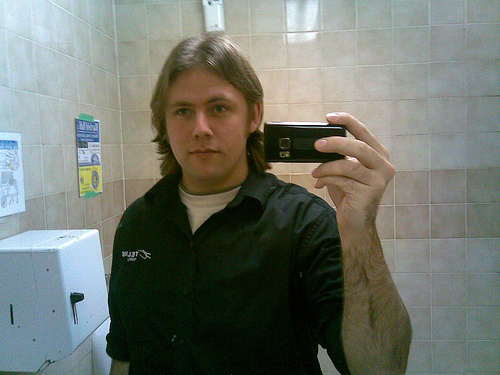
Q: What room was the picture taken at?
A: It was taken at the bathroom.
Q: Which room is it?
A: It is a bathroom.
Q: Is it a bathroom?
A: Yes, it is a bathroom.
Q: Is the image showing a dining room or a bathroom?
A: It is showing a bathroom.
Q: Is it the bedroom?
A: No, it is the bathroom.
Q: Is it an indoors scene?
A: Yes, it is indoors.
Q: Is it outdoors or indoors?
A: It is indoors.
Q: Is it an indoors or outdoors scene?
A: It is indoors.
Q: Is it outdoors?
A: No, it is indoors.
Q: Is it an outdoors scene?
A: No, it is indoors.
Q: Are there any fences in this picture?
A: No, there are no fences.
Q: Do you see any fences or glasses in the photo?
A: No, there are no fences or glasses.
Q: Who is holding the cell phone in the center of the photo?
A: The man is holding the cell phone.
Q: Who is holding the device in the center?
A: The man is holding the cell phone.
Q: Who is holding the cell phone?
A: The man is holding the cell phone.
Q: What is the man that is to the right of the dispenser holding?
A: The man is holding the cell phone.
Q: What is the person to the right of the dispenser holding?
A: The man is holding the cell phone.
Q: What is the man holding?
A: The man is holding the cell phone.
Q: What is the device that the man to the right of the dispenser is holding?
A: The device is a cell phone.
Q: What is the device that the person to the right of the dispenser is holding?
A: The device is a cell phone.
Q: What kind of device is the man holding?
A: The man is holding the cellphone.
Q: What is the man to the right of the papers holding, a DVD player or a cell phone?
A: The man is holding a cell phone.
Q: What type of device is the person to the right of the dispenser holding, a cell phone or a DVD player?
A: The man is holding a cell phone.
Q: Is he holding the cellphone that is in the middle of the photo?
A: Yes, the man is holding the cell phone.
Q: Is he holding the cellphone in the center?
A: Yes, the man is holding the cell phone.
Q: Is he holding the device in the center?
A: Yes, the man is holding the cell phone.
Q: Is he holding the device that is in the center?
A: Yes, the man is holding the cell phone.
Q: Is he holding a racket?
A: No, the man is holding the cell phone.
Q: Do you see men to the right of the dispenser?
A: Yes, there is a man to the right of the dispenser.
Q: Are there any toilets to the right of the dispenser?
A: No, there is a man to the right of the dispenser.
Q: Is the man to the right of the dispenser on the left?
A: Yes, the man is to the right of the dispenser.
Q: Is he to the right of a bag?
A: No, the man is to the right of the dispenser.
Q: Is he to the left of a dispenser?
A: No, the man is to the right of a dispenser.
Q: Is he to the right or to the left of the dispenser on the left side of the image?
A: The man is to the right of the dispenser.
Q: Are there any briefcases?
A: No, there are no briefcases.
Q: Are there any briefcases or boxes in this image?
A: No, there are no briefcases or boxes.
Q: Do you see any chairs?
A: No, there are no chairs.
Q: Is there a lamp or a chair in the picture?
A: No, there are no chairs or lamps.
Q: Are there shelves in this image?
A: No, there are no shelves.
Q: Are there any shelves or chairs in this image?
A: No, there are no shelves or chairs.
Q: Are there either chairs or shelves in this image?
A: No, there are no shelves or chairs.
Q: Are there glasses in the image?
A: No, there are no glasses.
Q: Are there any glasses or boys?
A: No, there are no glasses or boys.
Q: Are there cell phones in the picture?
A: Yes, there is a cell phone.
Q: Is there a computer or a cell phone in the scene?
A: Yes, there is a cell phone.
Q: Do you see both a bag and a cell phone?
A: No, there is a cell phone but no bags.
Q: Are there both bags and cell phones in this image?
A: No, there is a cell phone but no bags.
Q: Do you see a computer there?
A: No, there are no computers.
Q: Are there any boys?
A: No, there are no boys.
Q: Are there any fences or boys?
A: No, there are no boys or fences.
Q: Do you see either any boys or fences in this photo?
A: No, there are no boys or fences.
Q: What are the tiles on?
A: The tiles are on the walls.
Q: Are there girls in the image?
A: No, there are no girls.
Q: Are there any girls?
A: No, there are no girls.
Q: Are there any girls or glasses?
A: No, there are no girls or glasses.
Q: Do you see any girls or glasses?
A: No, there are no girls or glasses.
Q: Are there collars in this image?
A: Yes, there is a collar.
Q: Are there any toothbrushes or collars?
A: Yes, there is a collar.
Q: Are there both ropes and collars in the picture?
A: No, there is a collar but no ropes.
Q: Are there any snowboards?
A: No, there are no snowboards.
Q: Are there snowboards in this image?
A: No, there are no snowboards.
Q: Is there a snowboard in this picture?
A: No, there are no snowboards.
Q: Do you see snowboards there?
A: No, there are no snowboards.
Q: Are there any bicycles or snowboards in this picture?
A: No, there are no snowboards or bicycles.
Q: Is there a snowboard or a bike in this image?
A: No, there are no snowboards or bikes.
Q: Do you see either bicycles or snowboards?
A: No, there are no snowboards or bicycles.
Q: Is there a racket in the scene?
A: No, there are no rackets.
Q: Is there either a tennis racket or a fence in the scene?
A: No, there are no rackets or fences.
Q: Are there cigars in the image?
A: No, there are no cigars.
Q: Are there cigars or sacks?
A: No, there are no cigars or sacks.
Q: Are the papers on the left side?
A: Yes, the papers are on the left of the image.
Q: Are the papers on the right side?
A: No, the papers are on the left of the image.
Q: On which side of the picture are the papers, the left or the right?
A: The papers are on the left of the image.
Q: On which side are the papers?
A: The papers are on the left of the image.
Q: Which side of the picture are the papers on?
A: The papers are on the left of the image.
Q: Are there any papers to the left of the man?
A: Yes, there are papers to the left of the man.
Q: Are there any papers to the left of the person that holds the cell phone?
A: Yes, there are papers to the left of the man.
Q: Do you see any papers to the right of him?
A: No, the papers are to the left of the man.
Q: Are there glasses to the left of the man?
A: No, there are papers to the left of the man.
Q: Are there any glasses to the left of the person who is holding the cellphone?
A: No, there are papers to the left of the man.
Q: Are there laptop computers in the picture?
A: No, there are no laptop computers.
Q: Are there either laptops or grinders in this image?
A: No, there are no laptops or grinders.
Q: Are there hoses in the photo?
A: No, there are no hoses.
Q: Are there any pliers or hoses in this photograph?
A: No, there are no hoses or pliers.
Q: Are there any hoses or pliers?
A: No, there are no hoses or pliers.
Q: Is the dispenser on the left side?
A: Yes, the dispenser is on the left of the image.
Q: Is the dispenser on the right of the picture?
A: No, the dispenser is on the left of the image.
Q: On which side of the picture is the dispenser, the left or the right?
A: The dispenser is on the left of the image.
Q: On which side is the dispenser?
A: The dispenser is on the left of the image.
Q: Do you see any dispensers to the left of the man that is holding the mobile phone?
A: Yes, there is a dispenser to the left of the man.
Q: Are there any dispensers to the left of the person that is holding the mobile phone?
A: Yes, there is a dispenser to the left of the man.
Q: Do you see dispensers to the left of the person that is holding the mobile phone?
A: Yes, there is a dispenser to the left of the man.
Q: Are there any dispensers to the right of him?
A: No, the dispenser is to the left of the man.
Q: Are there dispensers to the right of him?
A: No, the dispenser is to the left of the man.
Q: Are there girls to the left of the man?
A: No, there is a dispenser to the left of the man.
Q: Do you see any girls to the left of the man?
A: No, there is a dispenser to the left of the man.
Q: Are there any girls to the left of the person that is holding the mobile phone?
A: No, there is a dispenser to the left of the man.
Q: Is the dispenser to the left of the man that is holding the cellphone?
A: Yes, the dispenser is to the left of the man.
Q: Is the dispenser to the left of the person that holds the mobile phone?
A: Yes, the dispenser is to the left of the man.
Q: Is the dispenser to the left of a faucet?
A: No, the dispenser is to the left of the man.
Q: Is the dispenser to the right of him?
A: No, the dispenser is to the left of the man.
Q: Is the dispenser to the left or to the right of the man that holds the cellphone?
A: The dispenser is to the left of the man.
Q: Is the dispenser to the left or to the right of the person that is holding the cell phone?
A: The dispenser is to the left of the man.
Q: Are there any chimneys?
A: No, there are no chimneys.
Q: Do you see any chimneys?
A: No, there are no chimneys.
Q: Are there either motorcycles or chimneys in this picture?
A: No, there are no chimneys or motorcycles.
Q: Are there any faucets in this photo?
A: No, there are no faucets.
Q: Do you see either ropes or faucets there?
A: No, there are no faucets or ropes.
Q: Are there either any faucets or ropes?
A: No, there are no faucets or ropes.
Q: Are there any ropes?
A: No, there are no ropes.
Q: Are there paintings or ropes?
A: No, there are no ropes or paintings.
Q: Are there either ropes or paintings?
A: No, there are no ropes or paintings.